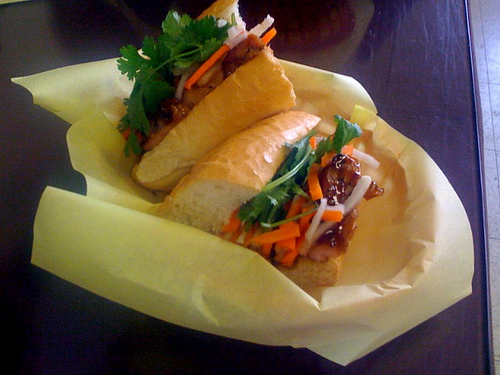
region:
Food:
[168, 127, 417, 287]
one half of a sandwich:
[178, 130, 425, 287]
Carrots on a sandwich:
[245, 191, 371, 291]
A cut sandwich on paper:
[50, 22, 428, 318]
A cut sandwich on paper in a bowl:
[74, 37, 465, 325]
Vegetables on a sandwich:
[160, 153, 408, 283]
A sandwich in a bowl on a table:
[272, 38, 418, 374]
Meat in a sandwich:
[301, 196, 369, 287]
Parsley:
[100, 19, 270, 159]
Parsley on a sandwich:
[92, 5, 282, 133]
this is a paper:
[100, 253, 172, 298]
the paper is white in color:
[91, 200, 132, 263]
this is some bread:
[205, 99, 249, 182]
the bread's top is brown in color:
[231, 137, 256, 166]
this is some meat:
[326, 162, 353, 189]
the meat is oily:
[326, 168, 338, 191]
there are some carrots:
[249, 230, 292, 247]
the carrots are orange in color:
[264, 237, 292, 253]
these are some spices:
[132, 51, 157, 96]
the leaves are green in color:
[143, 55, 163, 94]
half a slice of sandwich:
[151, 122, 406, 341]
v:
[169, 112, 364, 267]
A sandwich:
[108, 6, 415, 283]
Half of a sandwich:
[181, 109, 408, 280]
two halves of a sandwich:
[114, 35, 384, 275]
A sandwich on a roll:
[178, 124, 401, 296]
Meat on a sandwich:
[297, 179, 361, 299]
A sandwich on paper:
[100, 46, 449, 322]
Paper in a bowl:
[292, 63, 471, 361]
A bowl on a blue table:
[319, 85, 480, 367]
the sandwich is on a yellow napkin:
[11, 36, 475, 361]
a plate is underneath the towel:
[81, 82, 447, 330]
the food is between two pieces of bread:
[165, 131, 353, 262]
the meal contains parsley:
[257, 123, 354, 223]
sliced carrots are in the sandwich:
[253, 224, 298, 246]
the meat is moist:
[325, 153, 376, 247]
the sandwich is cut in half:
[112, 1, 364, 276]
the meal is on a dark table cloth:
[8, 2, 498, 367]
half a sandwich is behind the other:
[112, 1, 364, 290]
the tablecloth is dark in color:
[1, 3, 479, 374]